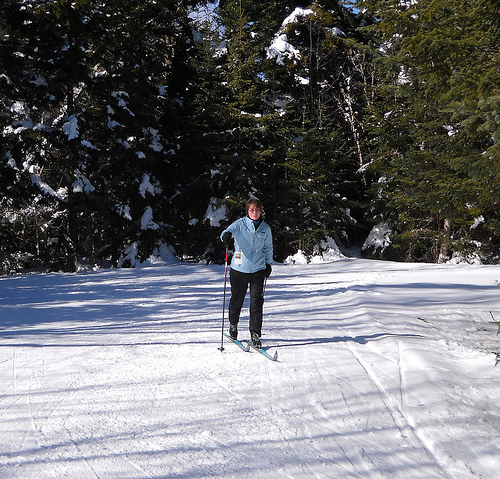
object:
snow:
[6, 280, 497, 475]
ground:
[9, 267, 494, 474]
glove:
[265, 263, 272, 278]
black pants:
[228, 271, 270, 332]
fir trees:
[388, 0, 500, 267]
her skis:
[224, 327, 252, 354]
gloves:
[222, 231, 232, 245]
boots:
[251, 332, 262, 348]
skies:
[224, 313, 280, 363]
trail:
[14, 277, 487, 477]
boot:
[229, 321, 238, 339]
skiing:
[149, 190, 366, 465]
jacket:
[220, 215, 274, 274]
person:
[219, 197, 273, 350]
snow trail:
[141, 254, 416, 462]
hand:
[222, 232, 233, 246]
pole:
[216, 242, 228, 354]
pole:
[260, 264, 268, 296]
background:
[19, 70, 469, 262]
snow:
[69, 86, 178, 265]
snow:
[249, 13, 308, 91]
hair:
[245, 197, 264, 215]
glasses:
[248, 207, 260, 212]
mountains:
[6, 4, 484, 469]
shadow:
[268, 331, 423, 347]